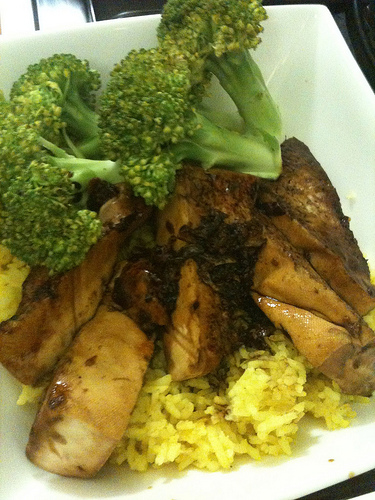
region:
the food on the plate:
[12, 44, 370, 421]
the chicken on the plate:
[235, 178, 352, 347]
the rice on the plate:
[157, 383, 291, 431]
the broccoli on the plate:
[108, 47, 289, 166]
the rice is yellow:
[159, 392, 303, 458]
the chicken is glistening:
[263, 191, 373, 331]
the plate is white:
[2, 40, 353, 485]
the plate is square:
[15, 15, 374, 441]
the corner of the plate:
[279, 1, 345, 50]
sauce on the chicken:
[126, 205, 272, 339]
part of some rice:
[174, 437, 205, 467]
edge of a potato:
[79, 408, 121, 464]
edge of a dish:
[319, 466, 347, 484]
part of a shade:
[112, 468, 136, 486]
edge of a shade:
[138, 482, 169, 497]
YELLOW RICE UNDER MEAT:
[106, 370, 351, 451]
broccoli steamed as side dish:
[115, 60, 268, 173]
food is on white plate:
[211, 470, 325, 498]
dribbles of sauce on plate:
[327, 456, 358, 476]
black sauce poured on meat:
[169, 214, 256, 298]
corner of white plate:
[304, 2, 337, 29]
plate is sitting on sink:
[68, 1, 154, 26]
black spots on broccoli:
[70, 180, 85, 203]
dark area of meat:
[287, 141, 319, 194]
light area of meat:
[58, 424, 91, 467]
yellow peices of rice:
[148, 385, 217, 443]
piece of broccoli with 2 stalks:
[97, 0, 309, 203]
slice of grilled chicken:
[24, 313, 151, 468]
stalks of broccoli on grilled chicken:
[90, 6, 360, 250]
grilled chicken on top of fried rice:
[124, 268, 253, 439]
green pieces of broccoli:
[19, 57, 284, 208]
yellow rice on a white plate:
[169, 436, 294, 498]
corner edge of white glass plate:
[252, 0, 360, 32]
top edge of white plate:
[40, 12, 141, 42]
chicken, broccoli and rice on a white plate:
[3, 32, 328, 399]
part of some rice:
[184, 435, 219, 487]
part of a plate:
[266, 460, 295, 491]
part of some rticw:
[277, 453, 293, 473]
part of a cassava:
[77, 399, 120, 463]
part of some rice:
[203, 391, 245, 446]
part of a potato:
[182, 366, 210, 382]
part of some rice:
[138, 417, 170, 459]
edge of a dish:
[304, 467, 340, 492]